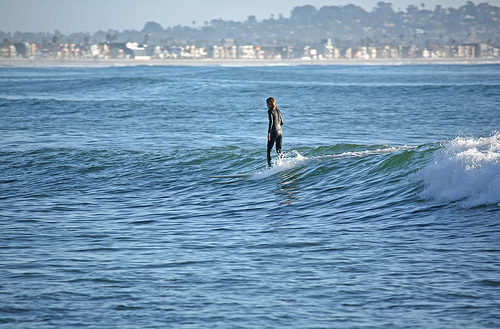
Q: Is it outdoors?
A: Yes, it is outdoors.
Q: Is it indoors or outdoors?
A: It is outdoors.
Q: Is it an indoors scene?
A: No, it is outdoors.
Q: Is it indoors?
A: No, it is outdoors.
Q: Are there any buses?
A: No, there are no buses.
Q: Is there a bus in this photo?
A: No, there are no buses.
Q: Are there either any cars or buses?
A: No, there are no buses or cars.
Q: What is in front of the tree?
A: The city is in front of the tree.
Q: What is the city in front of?
A: The city is in front of the tree.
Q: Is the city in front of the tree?
A: Yes, the city is in front of the tree.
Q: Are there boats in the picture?
A: No, there are no boats.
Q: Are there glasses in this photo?
A: No, there are no glasses.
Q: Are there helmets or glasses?
A: No, there are no glasses or helmets.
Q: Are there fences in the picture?
A: No, there are no fences.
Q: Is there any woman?
A: Yes, there is a woman.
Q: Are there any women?
A: Yes, there is a woman.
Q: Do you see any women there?
A: Yes, there is a woman.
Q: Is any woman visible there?
A: Yes, there is a woman.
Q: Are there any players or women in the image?
A: Yes, there is a woman.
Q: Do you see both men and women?
A: No, there is a woman but no men.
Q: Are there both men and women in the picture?
A: No, there is a woman but no men.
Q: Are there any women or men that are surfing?
A: Yes, the woman is surfing.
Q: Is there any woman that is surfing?
A: Yes, there is a woman that is surfing.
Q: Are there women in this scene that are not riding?
A: Yes, there is a woman that is surfing.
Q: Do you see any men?
A: No, there are no men.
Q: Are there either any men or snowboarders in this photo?
A: No, there are no men or snowboarders.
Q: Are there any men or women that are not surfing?
A: No, there is a woman but she is surfing.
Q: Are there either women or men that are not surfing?
A: No, there is a woman but she is surfing.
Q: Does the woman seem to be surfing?
A: Yes, the woman is surfing.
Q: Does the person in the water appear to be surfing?
A: Yes, the woman is surfing.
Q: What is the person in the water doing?
A: The woman is surfing.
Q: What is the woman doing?
A: The woman is surfing.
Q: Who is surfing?
A: The woman is surfing.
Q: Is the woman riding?
A: No, the woman is surfing.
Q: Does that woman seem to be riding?
A: No, the woman is surfing.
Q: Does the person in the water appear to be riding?
A: No, the woman is surfing.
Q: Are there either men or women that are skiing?
A: No, there is a woman but she is surfing.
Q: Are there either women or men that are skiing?
A: No, there is a woman but she is surfing.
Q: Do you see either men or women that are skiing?
A: No, there is a woman but she is surfing.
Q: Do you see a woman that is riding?
A: No, there is a woman but she is surfing.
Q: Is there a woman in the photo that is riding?
A: No, there is a woman but she is surfing.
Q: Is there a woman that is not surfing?
A: No, there is a woman but she is surfing.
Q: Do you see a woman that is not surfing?
A: No, there is a woman but she is surfing.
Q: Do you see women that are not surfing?
A: No, there is a woman but she is surfing.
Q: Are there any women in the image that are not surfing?
A: No, there is a woman but she is surfing.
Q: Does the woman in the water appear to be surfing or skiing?
A: The woman is surfing.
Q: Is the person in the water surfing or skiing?
A: The woman is surfing.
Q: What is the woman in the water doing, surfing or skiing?
A: The woman is surfing.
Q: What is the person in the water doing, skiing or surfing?
A: The woman is surfing.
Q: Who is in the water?
A: The woman is in the water.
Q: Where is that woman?
A: The woman is in the water.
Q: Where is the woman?
A: The woman is in the water.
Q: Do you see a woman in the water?
A: Yes, there is a woman in the water.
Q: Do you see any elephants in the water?
A: No, there is a woman in the water.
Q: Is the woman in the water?
A: Yes, the woman is in the water.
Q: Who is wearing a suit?
A: The woman is wearing a suit.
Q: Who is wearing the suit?
A: The woman is wearing a suit.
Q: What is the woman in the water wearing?
A: The woman is wearing a suit.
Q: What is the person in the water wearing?
A: The woman is wearing a suit.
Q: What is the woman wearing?
A: The woman is wearing a suit.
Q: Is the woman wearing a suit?
A: Yes, the woman is wearing a suit.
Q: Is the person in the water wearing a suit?
A: Yes, the woman is wearing a suit.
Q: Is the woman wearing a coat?
A: No, the woman is wearing a suit.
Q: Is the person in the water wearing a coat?
A: No, the woman is wearing a suit.